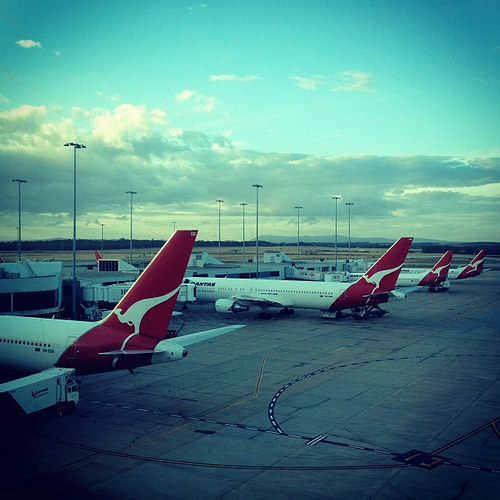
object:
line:
[251, 353, 269, 399]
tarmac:
[0, 268, 499, 497]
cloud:
[0, 110, 498, 218]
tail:
[350, 236, 414, 311]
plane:
[180, 237, 413, 323]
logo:
[108, 281, 184, 365]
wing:
[230, 291, 287, 310]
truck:
[426, 276, 451, 296]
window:
[266, 269, 279, 277]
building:
[282, 258, 367, 278]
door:
[64, 335, 78, 361]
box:
[393, 448, 447, 471]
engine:
[213, 296, 249, 316]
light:
[62, 142, 87, 150]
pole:
[70, 147, 77, 323]